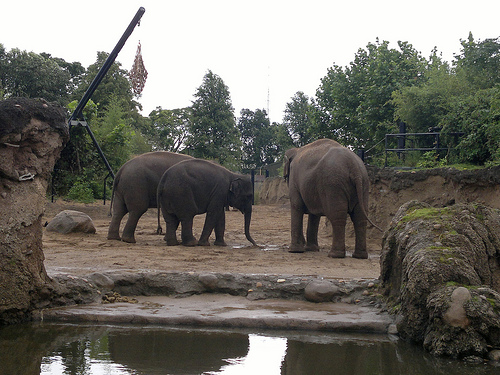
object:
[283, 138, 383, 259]
elephant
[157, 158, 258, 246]
elephant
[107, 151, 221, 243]
elephant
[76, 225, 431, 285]
pen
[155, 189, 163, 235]
tail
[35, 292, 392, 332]
step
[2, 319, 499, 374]
elephants water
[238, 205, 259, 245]
trunk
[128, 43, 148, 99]
net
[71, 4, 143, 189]
winch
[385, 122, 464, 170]
fence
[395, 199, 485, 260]
moss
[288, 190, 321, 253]
legs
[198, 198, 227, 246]
legs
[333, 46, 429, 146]
leaves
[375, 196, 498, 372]
stone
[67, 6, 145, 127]
pole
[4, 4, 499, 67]
sky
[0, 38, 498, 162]
green tree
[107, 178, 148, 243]
legs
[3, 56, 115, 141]
foliage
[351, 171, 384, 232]
tail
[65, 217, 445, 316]
ground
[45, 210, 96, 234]
boulder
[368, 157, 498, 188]
ledge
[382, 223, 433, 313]
dirt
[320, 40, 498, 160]
trees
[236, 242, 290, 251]
watering hole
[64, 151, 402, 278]
area